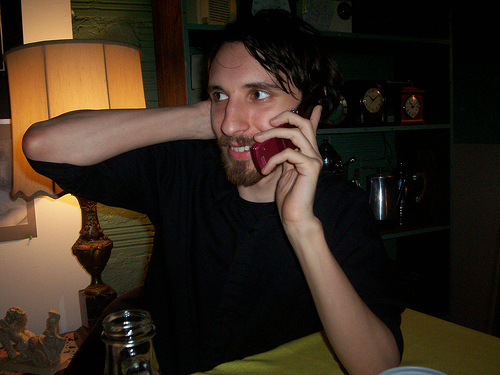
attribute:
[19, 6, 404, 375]
man — talking, smiling, young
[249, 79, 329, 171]
cellphone — red, orange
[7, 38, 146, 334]
lamp — yellow, brown, on, orange, curved, turned on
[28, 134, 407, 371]
shirt — black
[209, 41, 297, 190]
face — bearded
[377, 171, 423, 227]
jar — glass, clear, open, silver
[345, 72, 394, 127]
clock — black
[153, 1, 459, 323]
shelf — blue, brown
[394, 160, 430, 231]
pitcher — metal, silver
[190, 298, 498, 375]
table cloth — yellow, green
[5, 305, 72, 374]
statue — white, small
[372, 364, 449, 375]
dish — white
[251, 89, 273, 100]
eye — white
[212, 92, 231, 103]
eye — white